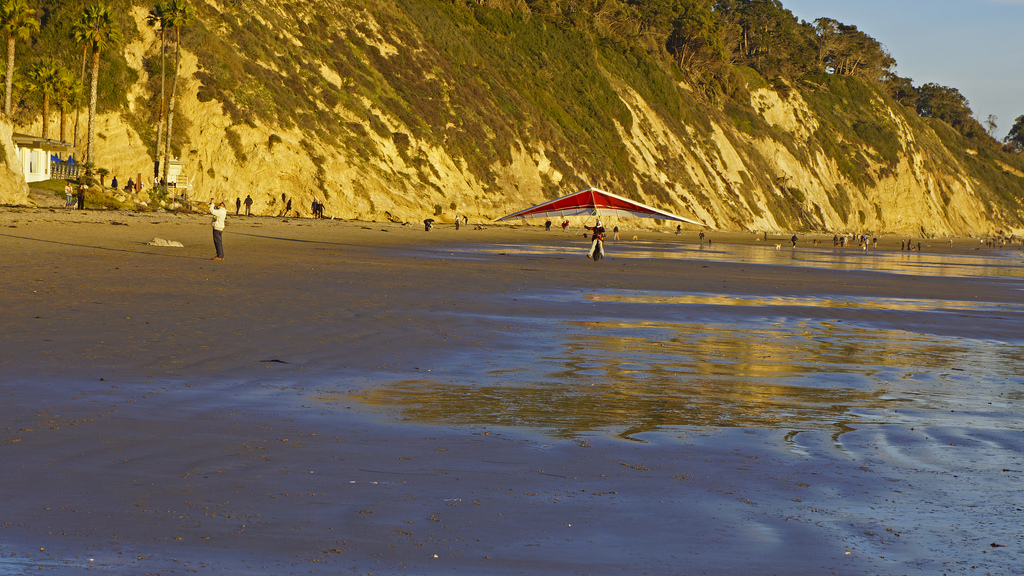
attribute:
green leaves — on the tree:
[736, 9, 780, 40]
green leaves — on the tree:
[818, 24, 860, 57]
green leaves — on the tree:
[764, 5, 786, 29]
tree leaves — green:
[677, 11, 740, 59]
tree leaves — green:
[675, 13, 745, 40]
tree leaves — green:
[813, 14, 840, 47]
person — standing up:
[207, 195, 231, 260]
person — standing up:
[200, 189, 240, 263]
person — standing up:
[204, 191, 231, 259]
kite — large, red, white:
[524, 173, 674, 226]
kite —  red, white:
[502, 185, 682, 229]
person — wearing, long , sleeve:
[195, 192, 237, 259]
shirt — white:
[203, 200, 230, 233]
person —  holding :
[579, 205, 619, 277]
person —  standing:
[203, 196, 242, 261]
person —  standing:
[575, 231, 621, 266]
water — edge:
[325, 252, 946, 551]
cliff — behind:
[188, 30, 955, 214]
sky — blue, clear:
[871, 0, 993, 98]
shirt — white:
[210, 207, 234, 225]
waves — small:
[711, 425, 992, 465]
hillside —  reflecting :
[199, 32, 992, 210]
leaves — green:
[750, 17, 884, 74]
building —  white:
[0, 140, 83, 208]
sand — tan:
[35, 222, 444, 262]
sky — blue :
[877, 15, 990, 85]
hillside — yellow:
[104, 17, 906, 203]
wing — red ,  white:
[527, 192, 651, 210]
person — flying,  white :
[582, 215, 613, 265]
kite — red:
[521, 164, 675, 231]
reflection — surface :
[532, 243, 993, 278]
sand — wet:
[566, 226, 949, 257]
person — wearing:
[191, 179, 243, 272]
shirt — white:
[204, 190, 231, 234]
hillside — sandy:
[262, 23, 831, 175]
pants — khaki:
[583, 233, 601, 264]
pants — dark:
[195, 226, 234, 272]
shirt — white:
[216, 213, 234, 233]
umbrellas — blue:
[86, 103, 186, 246]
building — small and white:
[22, 129, 62, 184]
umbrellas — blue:
[101, 205, 173, 229]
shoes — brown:
[210, 248, 236, 261]